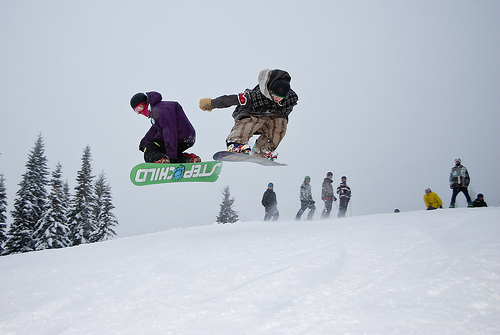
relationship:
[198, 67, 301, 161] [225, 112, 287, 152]
man with plaid pants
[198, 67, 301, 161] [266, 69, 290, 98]
man with hat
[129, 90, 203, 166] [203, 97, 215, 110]
man with gloves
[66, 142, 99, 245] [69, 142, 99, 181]
pine tree creates an outline in sky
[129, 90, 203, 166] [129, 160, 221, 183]
man riding snowboard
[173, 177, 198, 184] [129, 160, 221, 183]
board edge lining snowboard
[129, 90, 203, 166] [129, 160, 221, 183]
man holding snowboard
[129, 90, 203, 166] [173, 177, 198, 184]
man holding board edge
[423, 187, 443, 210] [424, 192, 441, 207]
man wearing coat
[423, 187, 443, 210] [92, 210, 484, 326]
man skiing on hill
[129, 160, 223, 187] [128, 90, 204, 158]
snowboard carries a snowboarder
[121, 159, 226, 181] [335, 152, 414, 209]
snowboard flies over ground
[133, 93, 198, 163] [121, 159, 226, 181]
man riding on snowboard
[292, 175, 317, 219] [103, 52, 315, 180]
man watching snowboarders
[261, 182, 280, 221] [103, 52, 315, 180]
man watching snowboarders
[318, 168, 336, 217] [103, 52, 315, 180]
man watching snowboarders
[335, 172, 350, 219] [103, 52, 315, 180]
man watching snowboarders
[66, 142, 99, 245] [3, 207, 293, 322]
pine tree are standing upon hill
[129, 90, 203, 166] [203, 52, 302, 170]
man midair with man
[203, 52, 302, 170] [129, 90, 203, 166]
man slightly ahead of man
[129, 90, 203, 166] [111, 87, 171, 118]
man wearing glasses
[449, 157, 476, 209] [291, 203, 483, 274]
man standing upon snow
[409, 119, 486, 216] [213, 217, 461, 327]
man bounding forward over snow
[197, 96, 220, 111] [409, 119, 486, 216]
hand balancing man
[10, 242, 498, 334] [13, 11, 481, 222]
snow blowing in wind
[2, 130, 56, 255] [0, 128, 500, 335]
pine tree rests on snow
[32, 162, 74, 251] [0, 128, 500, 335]
pine tree rests on snow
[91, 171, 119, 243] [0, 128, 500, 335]
pine tree rests on snow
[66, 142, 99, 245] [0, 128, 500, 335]
pine tree rests on snow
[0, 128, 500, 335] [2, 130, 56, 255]
snow beautifies pine tree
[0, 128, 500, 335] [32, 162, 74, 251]
snow beautifies pine tree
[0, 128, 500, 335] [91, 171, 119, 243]
snow beautifies pine tree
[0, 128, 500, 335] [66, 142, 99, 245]
snow beautifies pine tree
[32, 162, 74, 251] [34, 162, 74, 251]
pine tree bears leaves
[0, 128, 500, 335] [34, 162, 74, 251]
snow coats leaves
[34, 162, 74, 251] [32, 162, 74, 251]
leaves hang from pine tree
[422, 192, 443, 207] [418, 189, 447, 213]
snow jacket warms man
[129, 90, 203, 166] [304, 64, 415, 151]
man in air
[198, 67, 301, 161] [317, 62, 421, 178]
man in air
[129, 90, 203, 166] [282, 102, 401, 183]
man in air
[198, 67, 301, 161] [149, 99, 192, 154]
man wearing jacket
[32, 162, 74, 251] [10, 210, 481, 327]
pine tree in snow